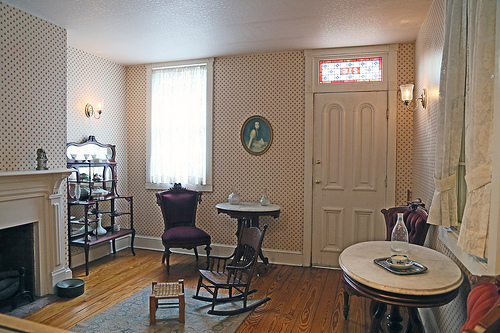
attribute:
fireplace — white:
[1, 167, 78, 318]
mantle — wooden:
[1, 148, 82, 183]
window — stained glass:
[316, 59, 385, 85]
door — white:
[307, 89, 392, 266]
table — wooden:
[338, 240, 464, 331]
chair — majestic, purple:
[150, 177, 210, 269]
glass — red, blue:
[319, 55, 384, 85]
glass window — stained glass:
[317, 58, 382, 83]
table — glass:
[287, 215, 452, 317]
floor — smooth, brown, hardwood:
[15, 247, 410, 332]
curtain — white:
[149, 68, 207, 185]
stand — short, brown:
[137, 277, 194, 329]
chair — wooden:
[192, 213, 274, 318]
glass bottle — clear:
[389, 212, 410, 255]